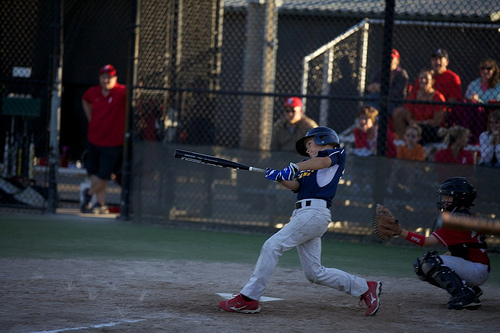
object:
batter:
[218, 127, 382, 316]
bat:
[174, 149, 267, 174]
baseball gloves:
[264, 162, 299, 182]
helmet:
[295, 126, 340, 156]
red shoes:
[219, 281, 381, 315]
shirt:
[291, 149, 346, 208]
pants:
[240, 199, 368, 301]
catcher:
[373, 179, 490, 311]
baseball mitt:
[375, 203, 402, 240]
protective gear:
[413, 251, 483, 310]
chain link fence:
[128, 0, 499, 251]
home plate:
[219, 294, 261, 314]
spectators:
[353, 49, 499, 167]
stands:
[300, 18, 500, 169]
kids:
[217, 126, 488, 317]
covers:
[219, 0, 500, 23]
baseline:
[37, 318, 144, 333]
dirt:
[0, 259, 500, 332]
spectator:
[270, 98, 319, 152]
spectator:
[414, 50, 460, 102]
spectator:
[465, 60, 500, 103]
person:
[404, 69, 451, 147]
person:
[433, 127, 474, 165]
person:
[478, 114, 500, 167]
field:
[0, 214, 500, 333]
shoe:
[219, 294, 261, 314]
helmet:
[436, 177, 478, 213]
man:
[80, 65, 126, 214]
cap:
[100, 64, 116, 76]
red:
[82, 82, 124, 145]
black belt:
[294, 200, 331, 209]